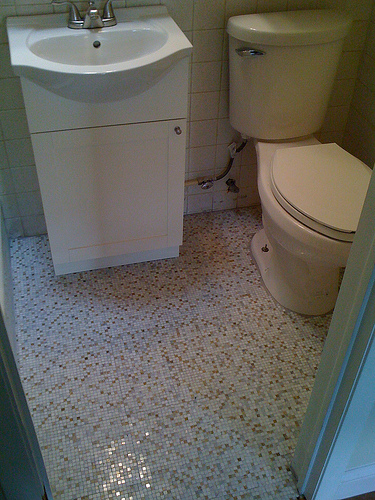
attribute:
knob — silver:
[164, 124, 195, 139]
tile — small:
[46, 356, 50, 361]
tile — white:
[193, 29, 221, 63]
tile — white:
[195, 63, 221, 90]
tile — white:
[192, 92, 217, 118]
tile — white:
[190, 121, 217, 146]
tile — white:
[189, 149, 213, 170]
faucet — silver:
[46, 4, 137, 37]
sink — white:
[2, 5, 195, 279]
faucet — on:
[49, 0, 125, 30]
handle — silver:
[236, 47, 267, 56]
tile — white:
[187, 16, 227, 161]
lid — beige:
[222, 6, 357, 50]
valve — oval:
[198, 178, 213, 191]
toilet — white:
[225, 9, 373, 315]